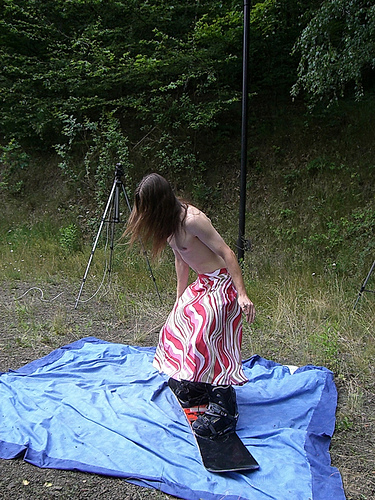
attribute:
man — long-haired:
[135, 171, 252, 435]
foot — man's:
[193, 386, 249, 441]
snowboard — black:
[167, 375, 260, 473]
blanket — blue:
[5, 332, 369, 494]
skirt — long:
[172, 285, 227, 340]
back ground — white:
[42, 358, 139, 450]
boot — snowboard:
[196, 385, 241, 455]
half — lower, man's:
[166, 271, 283, 396]